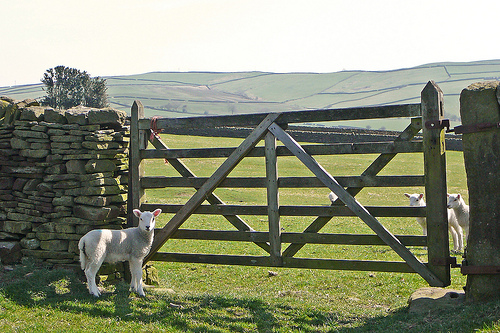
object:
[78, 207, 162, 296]
lamb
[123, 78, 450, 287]
gate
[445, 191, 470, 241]
lamb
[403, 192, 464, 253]
lamb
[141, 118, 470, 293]
pasture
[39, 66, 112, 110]
tree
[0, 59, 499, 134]
hillside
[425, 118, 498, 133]
hinge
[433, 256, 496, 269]
hinge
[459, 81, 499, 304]
wall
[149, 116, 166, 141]
cloth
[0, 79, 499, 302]
stone way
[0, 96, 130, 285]
wall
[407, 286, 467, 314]
rock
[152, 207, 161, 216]
ear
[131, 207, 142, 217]
ear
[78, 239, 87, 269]
tail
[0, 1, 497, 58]
sky